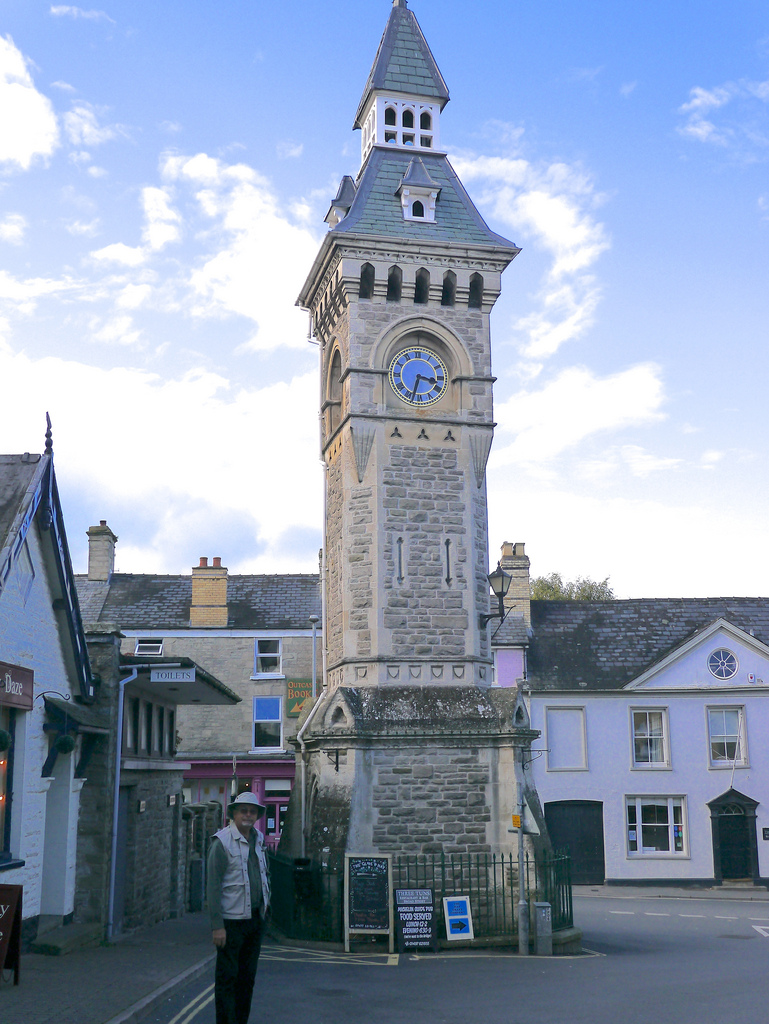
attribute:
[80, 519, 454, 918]
building — tan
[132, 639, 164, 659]
window — clear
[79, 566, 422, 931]
building — tan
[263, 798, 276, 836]
window — clear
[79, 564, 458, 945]
building — tan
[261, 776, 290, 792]
window — clear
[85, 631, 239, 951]
building — tan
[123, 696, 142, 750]
window — clear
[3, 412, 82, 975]
building — white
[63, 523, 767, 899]
building — white, tan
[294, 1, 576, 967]
tower — tan, tall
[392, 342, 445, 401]
clock — round, blue, black, gold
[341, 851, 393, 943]
sign — chalkboard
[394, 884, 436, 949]
sign — black , white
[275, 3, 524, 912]
tower — tall, brick, tan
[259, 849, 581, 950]
fence — black, metal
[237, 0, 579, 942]
tower — tall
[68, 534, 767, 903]
buildings — tan, white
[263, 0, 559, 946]
tower — tall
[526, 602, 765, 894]
building — white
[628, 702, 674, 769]
window — clear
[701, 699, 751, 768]
window — clear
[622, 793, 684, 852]
window — clear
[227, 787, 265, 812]
hat — tan